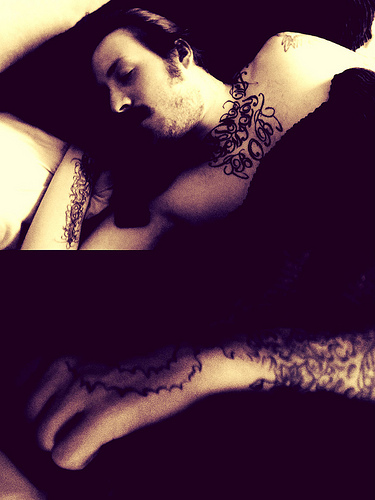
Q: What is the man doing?
A: Sleeping.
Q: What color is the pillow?
A: Black.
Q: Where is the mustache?
A: On the man's face.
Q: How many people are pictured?
A: One.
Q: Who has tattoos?
A: The sleeping man.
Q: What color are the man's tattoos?
A: Black.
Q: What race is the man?
A: White.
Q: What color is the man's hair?
A: Dark brown.